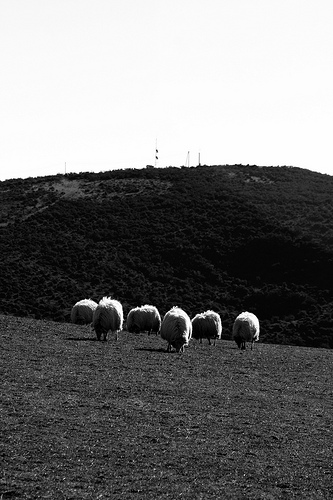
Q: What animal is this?
A: Sheep.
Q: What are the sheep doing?
A: Grazing.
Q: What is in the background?
A: A hill.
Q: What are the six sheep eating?
A: Grass.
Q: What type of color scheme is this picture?
A: Black and white.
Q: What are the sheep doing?
A: Grazing.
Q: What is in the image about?
A: Sheep.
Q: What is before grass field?
A: Hill top.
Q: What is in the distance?
A: Hill.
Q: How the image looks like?
A: Interesting.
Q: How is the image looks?
A: Black and white.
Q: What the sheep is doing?
A: Grazing.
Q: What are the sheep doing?
A: Grazing.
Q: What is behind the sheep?
A: Bushy hills.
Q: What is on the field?
A: Green grass.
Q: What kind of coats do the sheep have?
A: Wool.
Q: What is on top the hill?
A: A building.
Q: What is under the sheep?
A: Shadows from the sun.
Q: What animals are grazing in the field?
A: Sheep.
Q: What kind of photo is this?
A: Black and white.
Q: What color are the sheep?
A: White.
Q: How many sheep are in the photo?
A: Six.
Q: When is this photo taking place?
A: Daytime.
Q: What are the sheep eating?
A: Grass.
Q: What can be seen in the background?
A: A hill.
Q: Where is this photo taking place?
A: In a pasture.